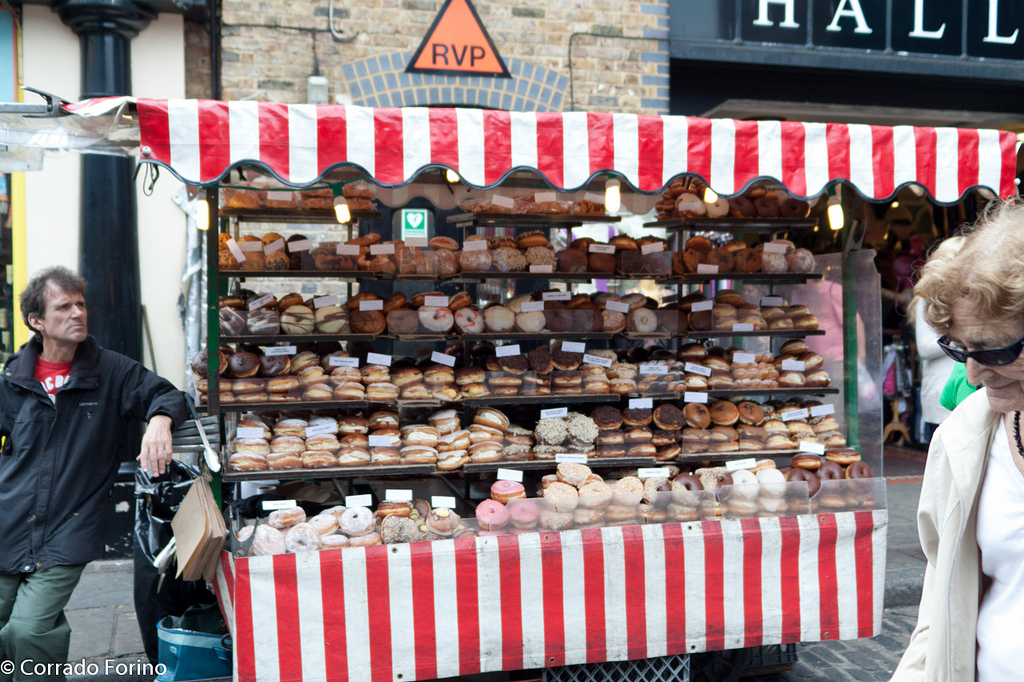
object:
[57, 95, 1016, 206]
cart roof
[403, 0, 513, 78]
triangle sign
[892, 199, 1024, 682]
people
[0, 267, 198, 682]
people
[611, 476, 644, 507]
doughnuts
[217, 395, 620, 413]
shelf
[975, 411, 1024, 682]
shirt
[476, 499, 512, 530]
food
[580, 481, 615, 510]
food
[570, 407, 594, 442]
food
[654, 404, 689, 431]
food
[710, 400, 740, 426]
food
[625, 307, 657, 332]
food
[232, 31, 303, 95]
wall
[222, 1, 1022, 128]
building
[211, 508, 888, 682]
cart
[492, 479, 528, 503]
donut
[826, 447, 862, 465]
donut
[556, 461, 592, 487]
donut